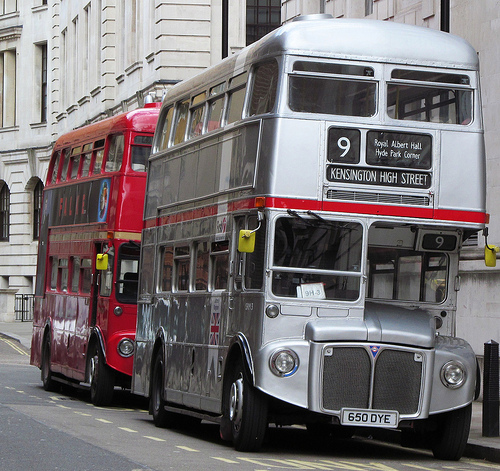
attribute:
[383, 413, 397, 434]
letter — black, white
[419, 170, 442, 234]
letter — white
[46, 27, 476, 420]
buses — parked on street, showing destination, 2 story, double decker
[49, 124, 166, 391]
bus — red, silver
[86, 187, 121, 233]
orange diamond — on post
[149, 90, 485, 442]
bus — in front, silver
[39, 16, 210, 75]
building — right of buses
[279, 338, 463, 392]
headlamps — off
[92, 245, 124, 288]
mirror — yellow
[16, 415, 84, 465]
street — portioned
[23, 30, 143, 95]
windows — in a row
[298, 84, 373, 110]
seats — abundant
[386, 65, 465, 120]
window — on level 2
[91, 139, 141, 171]
window — on 2nd level, on level 2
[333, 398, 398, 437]
tag — gray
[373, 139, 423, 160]
word — white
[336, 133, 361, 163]
banner — black